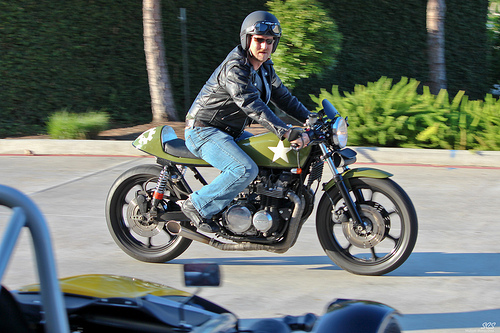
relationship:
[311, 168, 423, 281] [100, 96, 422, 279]
wheel of bike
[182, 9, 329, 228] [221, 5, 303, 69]
man wearing helmet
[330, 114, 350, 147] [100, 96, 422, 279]
headlight on bike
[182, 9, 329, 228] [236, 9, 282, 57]
man wearing helmet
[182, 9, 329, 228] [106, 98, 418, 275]
man riding motorcycle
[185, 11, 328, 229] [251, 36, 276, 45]
man wearing goggles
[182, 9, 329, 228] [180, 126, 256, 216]
man wearing jeans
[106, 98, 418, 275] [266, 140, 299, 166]
motorcycle has white star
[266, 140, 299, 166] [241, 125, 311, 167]
white star on tank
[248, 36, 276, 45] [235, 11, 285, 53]
goggles on front helmet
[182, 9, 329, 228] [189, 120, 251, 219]
man wearing jeans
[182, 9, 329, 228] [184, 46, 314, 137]
man wearing jacket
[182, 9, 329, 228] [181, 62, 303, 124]
man has jacket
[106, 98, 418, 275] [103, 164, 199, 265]
motorcycle with rear wheel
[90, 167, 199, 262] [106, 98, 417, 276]
rear wheel on motorcycle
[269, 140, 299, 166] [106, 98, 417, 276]
white star on motorcycle